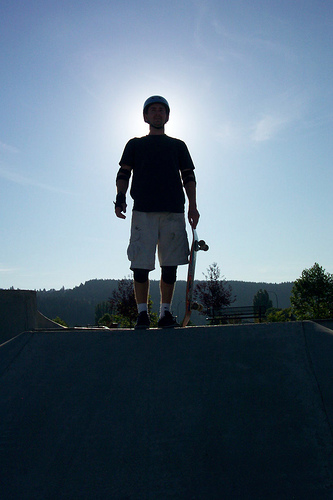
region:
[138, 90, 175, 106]
The helmet the guy is wearing.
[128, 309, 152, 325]
The left sneaker on the guy's foot.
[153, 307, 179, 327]
The right sneaker on the guy's foot.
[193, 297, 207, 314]
The back wheels of the skateboard.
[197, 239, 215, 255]
The front wheels of the skateboard.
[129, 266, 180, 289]
The black knee pads the guy is wearing.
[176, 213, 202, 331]
The skateboard the guy has his hand on.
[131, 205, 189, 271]
The shorts the guy is wearing.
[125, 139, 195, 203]
The t-shirt the guy is wearing.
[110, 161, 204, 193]
The elbow pads the guy is wearing.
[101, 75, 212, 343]
A man standing on top of a skateboard jump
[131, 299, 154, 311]
White athletic male sock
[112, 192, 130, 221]
A wrist brace for protection when falling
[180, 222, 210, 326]
A colorful four wheeled skateboard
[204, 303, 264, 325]
A green park bench in the distance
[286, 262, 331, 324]
Green shrubbery growing in a park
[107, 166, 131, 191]
Elbow pads worn for protection during falling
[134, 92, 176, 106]
Safety equipment helment to protect the skater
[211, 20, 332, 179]
A light blue cloudless sky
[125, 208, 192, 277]
Light khaki cargo shorts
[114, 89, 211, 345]
A man standing with a skate board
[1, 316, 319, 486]
A thick piece of concrete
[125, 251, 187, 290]
A pair of black knee pads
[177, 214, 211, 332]
A skate board with 4 wheels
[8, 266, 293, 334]
A thick tree line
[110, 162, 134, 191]
A single black elbow pad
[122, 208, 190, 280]
A guys pair of shorts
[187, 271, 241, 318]
A tree with leafs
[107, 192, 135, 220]
A hand cast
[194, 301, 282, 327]
A black park bench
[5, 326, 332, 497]
a tall concrete wall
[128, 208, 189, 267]
a pair of men's white shorts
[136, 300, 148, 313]
a man's white sock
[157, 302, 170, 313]
a man's white sock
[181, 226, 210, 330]
a skateboard standing on end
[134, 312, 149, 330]
a man's athletic shoe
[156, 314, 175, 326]
a man's athletic shoe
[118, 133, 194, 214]
a man's t-shirt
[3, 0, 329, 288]
a light blue sky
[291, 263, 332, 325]
a green tree in distance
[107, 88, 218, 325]
the man standing on the ramp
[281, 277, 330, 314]
the tree with green leaves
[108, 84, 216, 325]
the man holding the skateboard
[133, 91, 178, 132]
the man wearing the helmet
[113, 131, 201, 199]
the man wearing elbow pads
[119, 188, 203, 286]
the man wearing cargo shorts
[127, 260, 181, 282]
the man wearing knee pads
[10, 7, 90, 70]
the clear blue sky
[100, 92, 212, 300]
the man is silhouetted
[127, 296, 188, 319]
the socks are white